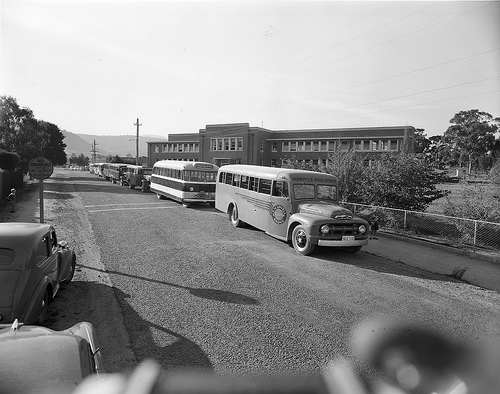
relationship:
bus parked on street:
[215, 165, 371, 257] [64, 167, 500, 393]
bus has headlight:
[215, 165, 371, 257] [321, 225, 330, 235]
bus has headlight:
[215, 165, 371, 257] [358, 225, 367, 234]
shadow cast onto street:
[45, 180, 147, 199] [64, 167, 500, 393]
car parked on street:
[0, 317, 104, 393] [64, 167, 500, 393]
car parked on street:
[0, 219, 77, 328] [64, 167, 500, 393]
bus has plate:
[215, 165, 371, 257] [344, 236, 356, 245]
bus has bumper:
[215, 165, 371, 257] [319, 239, 371, 247]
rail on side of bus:
[151, 173, 187, 184] [151, 157, 219, 208]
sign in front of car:
[28, 157, 56, 222] [0, 219, 77, 328]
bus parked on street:
[102, 164, 127, 185] [64, 167, 500, 393]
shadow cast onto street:
[76, 262, 259, 307] [64, 167, 500, 393]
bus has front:
[215, 165, 371, 257] [289, 174, 372, 257]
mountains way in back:
[59, 127, 167, 163] [3, 4, 497, 190]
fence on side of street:
[337, 201, 499, 253] [64, 167, 500, 393]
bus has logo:
[215, 165, 371, 257] [235, 192, 289, 226]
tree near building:
[416, 128, 426, 151] [148, 122, 417, 180]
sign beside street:
[28, 157, 56, 222] [64, 167, 500, 393]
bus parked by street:
[92, 164, 103, 175] [64, 167, 500, 393]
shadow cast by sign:
[76, 262, 259, 307] [28, 157, 56, 222]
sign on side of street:
[28, 157, 56, 222] [64, 167, 500, 393]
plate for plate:
[344, 236, 356, 245] [342, 235, 355, 243]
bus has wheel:
[215, 165, 371, 257] [291, 224, 320, 256]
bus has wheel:
[215, 165, 371, 257] [343, 246, 363, 254]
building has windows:
[148, 122, 417, 180] [211, 139, 245, 152]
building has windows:
[148, 122, 417, 180] [382, 139, 397, 152]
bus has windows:
[215, 165, 371, 257] [219, 172, 290, 200]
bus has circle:
[215, 165, 371, 257] [270, 204, 288, 224]